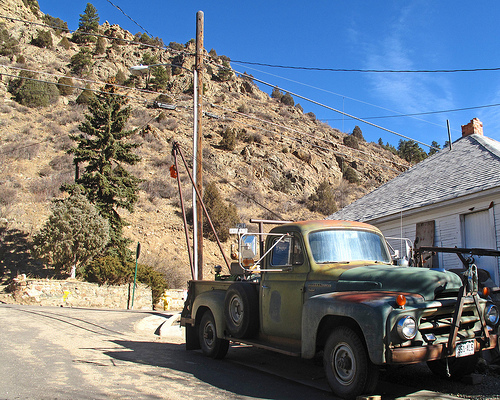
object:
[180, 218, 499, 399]
truck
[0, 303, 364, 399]
dirt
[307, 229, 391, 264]
windshield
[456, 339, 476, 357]
license plate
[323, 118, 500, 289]
building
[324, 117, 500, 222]
grey roof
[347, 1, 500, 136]
cloud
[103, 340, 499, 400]
shadow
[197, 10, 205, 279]
pole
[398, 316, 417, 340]
light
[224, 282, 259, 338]
spare tire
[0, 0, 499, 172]
power lines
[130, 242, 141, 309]
stop sign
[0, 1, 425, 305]
hill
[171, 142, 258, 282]
towing equipment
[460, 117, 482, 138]
chimney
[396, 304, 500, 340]
headlights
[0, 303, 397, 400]
road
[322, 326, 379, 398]
front tire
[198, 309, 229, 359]
rear tire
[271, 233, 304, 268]
window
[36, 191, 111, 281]
tree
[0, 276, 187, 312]
wall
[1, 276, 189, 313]
stone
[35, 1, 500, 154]
blue sky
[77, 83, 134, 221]
trees